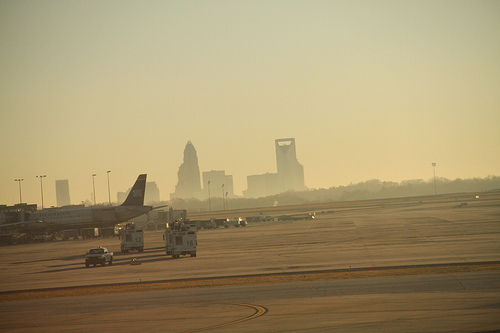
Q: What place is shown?
A: It is an airport.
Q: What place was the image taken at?
A: It was taken at the airport.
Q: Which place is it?
A: It is an airport.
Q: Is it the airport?
A: Yes, it is the airport.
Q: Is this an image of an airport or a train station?
A: It is showing an airport.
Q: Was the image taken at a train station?
A: No, the picture was taken in an airport.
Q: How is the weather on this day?
A: It is cloudy.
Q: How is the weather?
A: It is cloudy.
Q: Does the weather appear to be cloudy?
A: Yes, it is cloudy.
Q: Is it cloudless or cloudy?
A: It is cloudy.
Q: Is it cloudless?
A: No, it is cloudy.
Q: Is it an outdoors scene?
A: Yes, it is outdoors.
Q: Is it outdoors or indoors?
A: It is outdoors.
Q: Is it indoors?
A: No, it is outdoors.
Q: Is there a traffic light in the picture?
A: No, there are no traffic lights.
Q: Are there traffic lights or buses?
A: No, there are no traffic lights or buses.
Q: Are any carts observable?
A: No, there are no carts.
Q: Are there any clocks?
A: No, there are no clocks.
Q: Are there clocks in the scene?
A: No, there are no clocks.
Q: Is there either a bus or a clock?
A: No, there are no clocks or buses.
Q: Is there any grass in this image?
A: Yes, there is grass.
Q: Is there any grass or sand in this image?
A: Yes, there is grass.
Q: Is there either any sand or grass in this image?
A: Yes, there is grass.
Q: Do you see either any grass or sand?
A: Yes, there is grass.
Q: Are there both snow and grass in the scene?
A: No, there is grass but no snow.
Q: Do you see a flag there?
A: No, there are no flags.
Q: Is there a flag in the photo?
A: No, there are no flags.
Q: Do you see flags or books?
A: No, there are no flags or books.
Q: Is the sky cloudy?
A: Yes, the sky is cloudy.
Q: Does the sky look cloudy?
A: Yes, the sky is cloudy.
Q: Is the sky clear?
A: No, the sky is cloudy.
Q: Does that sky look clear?
A: No, the sky is cloudy.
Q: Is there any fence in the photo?
A: No, there are no fences.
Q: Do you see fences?
A: No, there are no fences.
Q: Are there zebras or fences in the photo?
A: No, there are no fences or zebras.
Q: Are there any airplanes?
A: Yes, there is an airplane.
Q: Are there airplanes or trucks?
A: Yes, there is an airplane.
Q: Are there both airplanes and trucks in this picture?
A: Yes, there are both an airplane and a truck.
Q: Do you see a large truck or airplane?
A: Yes, there is a large airplane.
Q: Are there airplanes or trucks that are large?
A: Yes, the airplane is large.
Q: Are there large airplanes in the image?
A: Yes, there is a large airplane.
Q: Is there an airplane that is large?
A: Yes, there is an airplane that is large.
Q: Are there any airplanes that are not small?
A: Yes, there is a large airplane.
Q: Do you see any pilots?
A: No, there are no pilots.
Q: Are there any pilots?
A: No, there are no pilots.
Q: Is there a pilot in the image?
A: No, there are no pilots.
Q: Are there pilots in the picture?
A: No, there are no pilots.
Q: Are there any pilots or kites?
A: No, there are no pilots or kites.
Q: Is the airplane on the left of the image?
A: Yes, the airplane is on the left of the image.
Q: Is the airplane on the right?
A: No, the airplane is on the left of the image.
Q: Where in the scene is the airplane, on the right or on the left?
A: The airplane is on the left of the image.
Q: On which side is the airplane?
A: The airplane is on the left of the image.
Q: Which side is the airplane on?
A: The airplane is on the left of the image.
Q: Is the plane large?
A: Yes, the plane is large.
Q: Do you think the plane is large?
A: Yes, the plane is large.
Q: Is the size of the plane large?
A: Yes, the plane is large.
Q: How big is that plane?
A: The plane is large.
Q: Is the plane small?
A: No, the plane is large.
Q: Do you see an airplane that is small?
A: No, there is an airplane but it is large.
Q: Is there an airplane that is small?
A: No, there is an airplane but it is large.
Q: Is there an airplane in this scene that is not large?
A: No, there is an airplane but it is large.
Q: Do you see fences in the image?
A: No, there are no fences.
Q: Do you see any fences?
A: No, there are no fences.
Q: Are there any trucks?
A: Yes, there is a truck.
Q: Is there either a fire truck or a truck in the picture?
A: Yes, there is a truck.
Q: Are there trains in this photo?
A: No, there are no trains.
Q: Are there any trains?
A: No, there are no trains.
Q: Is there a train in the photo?
A: No, there are no trains.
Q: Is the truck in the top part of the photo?
A: No, the truck is in the bottom of the image.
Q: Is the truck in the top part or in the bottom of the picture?
A: The truck is in the bottom of the image.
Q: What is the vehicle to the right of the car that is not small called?
A: The vehicle is a truck.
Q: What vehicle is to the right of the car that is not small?
A: The vehicle is a truck.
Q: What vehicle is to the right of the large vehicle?
A: The vehicle is a truck.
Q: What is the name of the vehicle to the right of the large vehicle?
A: The vehicle is a truck.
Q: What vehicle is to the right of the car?
A: The vehicle is a truck.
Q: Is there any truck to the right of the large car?
A: Yes, there is a truck to the right of the car.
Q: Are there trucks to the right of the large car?
A: Yes, there is a truck to the right of the car.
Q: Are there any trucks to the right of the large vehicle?
A: Yes, there is a truck to the right of the car.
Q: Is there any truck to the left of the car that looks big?
A: No, the truck is to the right of the car.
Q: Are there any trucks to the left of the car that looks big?
A: No, the truck is to the right of the car.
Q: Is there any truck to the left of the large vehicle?
A: No, the truck is to the right of the car.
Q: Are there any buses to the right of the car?
A: No, there is a truck to the right of the car.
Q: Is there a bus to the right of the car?
A: No, there is a truck to the right of the car.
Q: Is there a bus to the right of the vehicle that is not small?
A: No, there is a truck to the right of the car.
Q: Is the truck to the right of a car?
A: Yes, the truck is to the right of a car.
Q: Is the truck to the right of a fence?
A: No, the truck is to the right of a car.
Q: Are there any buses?
A: No, there are no buses.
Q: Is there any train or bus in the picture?
A: No, there are no buses or trains.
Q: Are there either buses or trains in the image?
A: No, there are no buses or trains.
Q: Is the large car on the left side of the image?
A: Yes, the car is on the left of the image.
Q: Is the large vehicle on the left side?
A: Yes, the car is on the left of the image.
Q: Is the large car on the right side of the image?
A: No, the car is on the left of the image.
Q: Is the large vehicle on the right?
A: No, the car is on the left of the image.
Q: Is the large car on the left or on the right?
A: The car is on the left of the image.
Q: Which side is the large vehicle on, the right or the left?
A: The car is on the left of the image.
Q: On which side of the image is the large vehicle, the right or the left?
A: The car is on the left of the image.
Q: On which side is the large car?
A: The car is on the left of the image.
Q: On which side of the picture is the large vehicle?
A: The car is on the left of the image.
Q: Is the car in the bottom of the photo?
A: Yes, the car is in the bottom of the image.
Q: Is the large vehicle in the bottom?
A: Yes, the car is in the bottom of the image.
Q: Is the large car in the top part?
A: No, the car is in the bottom of the image.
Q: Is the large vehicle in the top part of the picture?
A: No, the car is in the bottom of the image.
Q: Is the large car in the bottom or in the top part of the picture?
A: The car is in the bottom of the image.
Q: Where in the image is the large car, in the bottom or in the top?
A: The car is in the bottom of the image.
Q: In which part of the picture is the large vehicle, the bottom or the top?
A: The car is in the bottom of the image.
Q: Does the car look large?
A: Yes, the car is large.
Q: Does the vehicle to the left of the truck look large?
A: Yes, the car is large.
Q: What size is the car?
A: The car is large.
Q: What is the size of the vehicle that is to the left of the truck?
A: The car is large.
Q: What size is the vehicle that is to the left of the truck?
A: The car is large.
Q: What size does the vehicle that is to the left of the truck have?
A: The car has large size.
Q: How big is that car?
A: The car is large.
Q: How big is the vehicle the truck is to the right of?
A: The car is large.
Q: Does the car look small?
A: No, the car is large.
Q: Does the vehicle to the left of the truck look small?
A: No, the car is large.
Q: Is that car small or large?
A: The car is large.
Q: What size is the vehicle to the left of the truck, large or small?
A: The car is large.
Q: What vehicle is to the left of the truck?
A: The vehicle is a car.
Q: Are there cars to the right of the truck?
A: No, the car is to the left of the truck.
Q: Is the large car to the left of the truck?
A: Yes, the car is to the left of the truck.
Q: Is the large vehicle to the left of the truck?
A: Yes, the car is to the left of the truck.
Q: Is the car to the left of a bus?
A: No, the car is to the left of the truck.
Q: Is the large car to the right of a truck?
A: No, the car is to the left of a truck.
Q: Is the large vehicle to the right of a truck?
A: No, the car is to the left of a truck.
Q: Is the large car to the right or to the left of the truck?
A: The car is to the left of the truck.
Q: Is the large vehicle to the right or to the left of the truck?
A: The car is to the left of the truck.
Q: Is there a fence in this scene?
A: No, there are no fences.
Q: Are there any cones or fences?
A: No, there are no fences or cones.